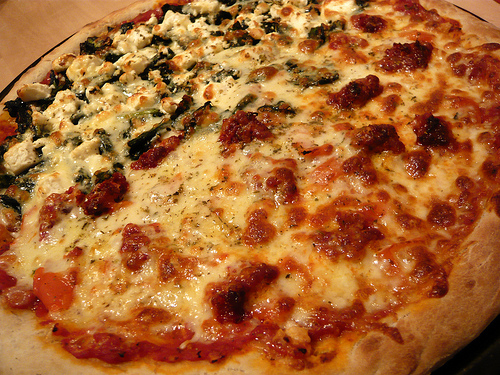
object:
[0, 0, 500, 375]
cheese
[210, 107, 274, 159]
meat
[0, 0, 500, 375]
pan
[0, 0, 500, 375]
table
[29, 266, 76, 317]
orange vegetable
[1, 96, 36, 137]
spinach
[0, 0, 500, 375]
cheesy pizza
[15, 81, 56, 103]
chicken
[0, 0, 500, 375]
halves